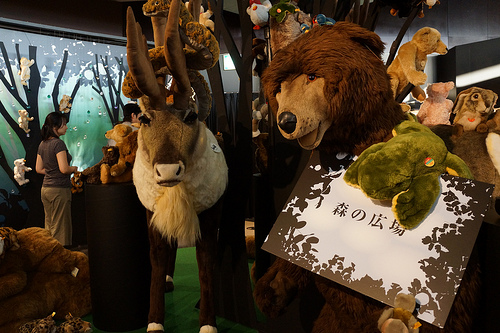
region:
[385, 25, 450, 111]
Stuffed bear on a fake tree limb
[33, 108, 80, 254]
A woman in brown standing beside stuffed animals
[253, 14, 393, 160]
A large, brown teddy bear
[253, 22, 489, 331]
A large teddy bear holding a sign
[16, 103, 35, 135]
Small teddy bear on a tree limb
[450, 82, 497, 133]
A small stuffed rabbit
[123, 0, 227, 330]
A large stuffed moose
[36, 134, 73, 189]
Brown shirt on a woman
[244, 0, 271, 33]
Stuffed bird on a tree branch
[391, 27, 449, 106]
A light brown stuffed bear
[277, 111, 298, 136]
bear has black nose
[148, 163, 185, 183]
deer has brown nose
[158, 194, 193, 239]
blonde hair on deer chin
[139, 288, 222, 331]
front legs of deer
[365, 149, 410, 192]
bear has green nose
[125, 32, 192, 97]
bottom of antlers on deer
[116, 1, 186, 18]
tip of deer antlers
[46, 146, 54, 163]
woman wearing brown shirt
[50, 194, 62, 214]
woman wearing beige skirt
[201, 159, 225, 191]
white fur on deers neck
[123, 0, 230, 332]
a toy stuffed goat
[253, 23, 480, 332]
a toy stuffed bear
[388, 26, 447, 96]
a stuffed teddy bear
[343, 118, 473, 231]
a green stuffed toy frog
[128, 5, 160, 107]
a toy goat's horns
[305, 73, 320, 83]
a toy bear's left eye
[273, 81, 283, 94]
a toy bear's right eye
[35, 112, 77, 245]
the back of an Asian woman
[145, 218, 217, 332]
a toy goat's front legs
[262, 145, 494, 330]
a black and white sign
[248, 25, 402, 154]
Large brown teddy bear head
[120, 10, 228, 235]
Large stuffed animal head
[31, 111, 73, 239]
Woman in a brown shirt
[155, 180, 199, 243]
Tan beard on stuffed head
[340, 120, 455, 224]
Green stuffed animal on board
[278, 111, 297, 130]
Black nose on stuffed bear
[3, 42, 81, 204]
Tree painted on wall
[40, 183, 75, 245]
Tan pants on woman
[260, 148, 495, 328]
Brown and white board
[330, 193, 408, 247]
Asian lettering on board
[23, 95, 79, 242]
woman at the counter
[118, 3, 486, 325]
stuffed toys around toy tree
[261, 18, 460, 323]
large stuffed bear with card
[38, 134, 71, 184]
blouse on the woman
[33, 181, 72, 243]
pants on the woman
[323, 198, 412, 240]
info on the card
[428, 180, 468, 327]
decorative border on card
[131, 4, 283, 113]
stuffed toys in the tree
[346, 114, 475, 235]
stuffed toy hanging over card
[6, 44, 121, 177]
display near the woman